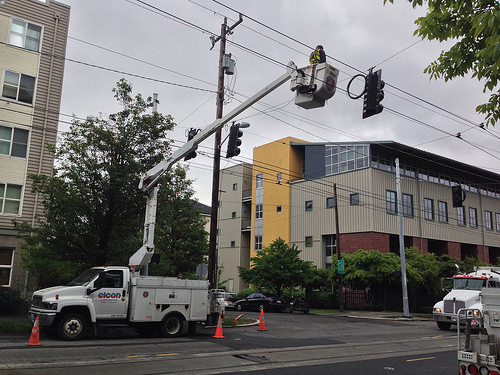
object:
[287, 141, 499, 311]
building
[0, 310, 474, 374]
ground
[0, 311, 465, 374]
pavement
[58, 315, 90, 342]
tire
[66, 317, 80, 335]
hub cap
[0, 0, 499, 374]
scene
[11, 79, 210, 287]
tree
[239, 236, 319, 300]
tree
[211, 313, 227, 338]
cones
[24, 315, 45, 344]
cones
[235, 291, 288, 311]
car